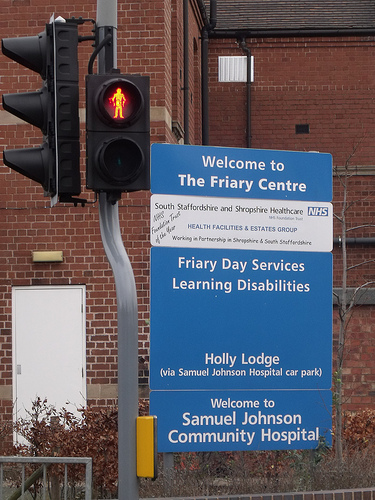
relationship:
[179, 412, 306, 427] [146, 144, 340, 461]
samuel johnson on sign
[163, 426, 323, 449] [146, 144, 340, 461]
community hospital on sign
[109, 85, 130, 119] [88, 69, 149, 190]
person outline on traffic light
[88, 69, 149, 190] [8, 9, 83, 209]
traffic light with traffic light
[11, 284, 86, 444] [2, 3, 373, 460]
door in building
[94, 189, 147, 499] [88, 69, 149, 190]
pole holding up traffic light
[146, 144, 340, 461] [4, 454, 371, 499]
sign above fencing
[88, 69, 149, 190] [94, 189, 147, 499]
traffic light on pole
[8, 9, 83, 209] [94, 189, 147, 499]
traffic light on pole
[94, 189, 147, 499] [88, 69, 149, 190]
pole for traffic light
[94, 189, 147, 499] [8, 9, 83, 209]
pole for traffic light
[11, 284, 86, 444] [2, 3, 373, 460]
door on building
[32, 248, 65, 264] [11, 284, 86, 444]
light above door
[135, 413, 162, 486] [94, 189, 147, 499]
box on pole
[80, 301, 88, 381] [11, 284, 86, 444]
hinges on door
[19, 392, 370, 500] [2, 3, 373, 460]
bushes next to building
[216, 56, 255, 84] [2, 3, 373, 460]
vent on building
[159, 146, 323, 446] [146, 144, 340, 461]
lettering on sign